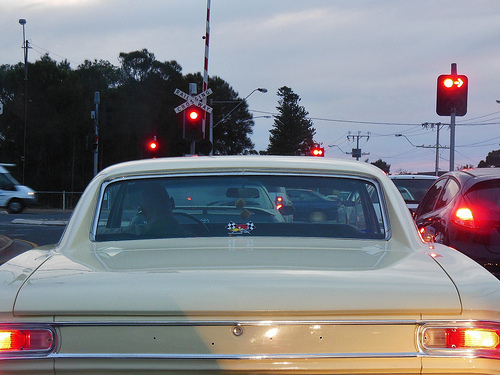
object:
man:
[97, 182, 197, 236]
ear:
[140, 205, 147, 217]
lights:
[188, 111, 199, 120]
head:
[136, 185, 175, 223]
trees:
[0, 48, 323, 211]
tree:
[198, 75, 255, 156]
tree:
[115, 47, 182, 153]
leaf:
[273, 106, 283, 110]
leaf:
[179, 67, 183, 71]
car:
[0, 154, 499, 375]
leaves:
[267, 84, 324, 155]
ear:
[169, 196, 176, 209]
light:
[0, 315, 497, 356]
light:
[447, 203, 475, 226]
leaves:
[0, 47, 259, 193]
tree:
[0, 57, 75, 210]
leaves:
[0, 48, 317, 177]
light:
[149, 142, 157, 150]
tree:
[73, 47, 182, 192]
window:
[89, 170, 393, 243]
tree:
[267, 85, 324, 156]